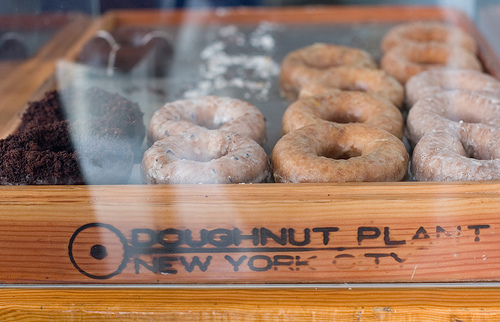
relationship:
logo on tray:
[65, 221, 490, 278] [2, 9, 498, 283]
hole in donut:
[180, 148, 228, 161] [141, 130, 268, 185]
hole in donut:
[318, 144, 360, 161] [270, 122, 410, 182]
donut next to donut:
[15, 83, 146, 158] [0, 110, 133, 185]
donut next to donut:
[405, 90, 499, 147] [408, 121, 498, 182]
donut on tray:
[65, 221, 131, 279] [2, 9, 498, 283]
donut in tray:
[141, 130, 268, 185] [2, 9, 498, 283]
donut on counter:
[280, 90, 402, 142] [2, 286, 498, 320]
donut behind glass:
[298, 64, 405, 106] [1, 0, 498, 287]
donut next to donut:
[298, 64, 405, 106] [280, 90, 402, 142]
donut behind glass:
[405, 90, 499, 147] [1, 0, 498, 287]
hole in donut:
[322, 110, 364, 124] [280, 90, 402, 142]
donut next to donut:
[408, 121, 498, 182] [405, 90, 499, 147]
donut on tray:
[141, 130, 268, 185] [2, 9, 498, 283]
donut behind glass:
[15, 83, 146, 158] [1, 0, 498, 287]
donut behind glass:
[141, 130, 268, 185] [1, 0, 498, 287]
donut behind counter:
[379, 41, 482, 84] [2, 286, 498, 320]